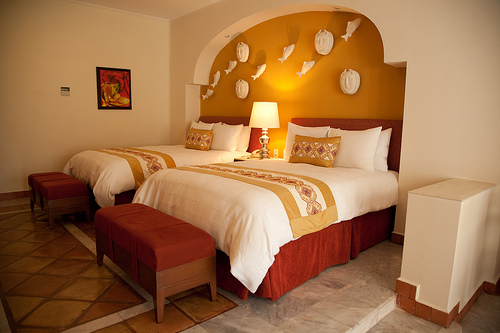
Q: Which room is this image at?
A: It is at the bedroom.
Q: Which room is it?
A: It is a bedroom.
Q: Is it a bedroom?
A: Yes, it is a bedroom.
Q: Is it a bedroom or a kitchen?
A: It is a bedroom.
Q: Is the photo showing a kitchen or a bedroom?
A: It is showing a bedroom.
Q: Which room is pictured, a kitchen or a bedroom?
A: It is a bedroom.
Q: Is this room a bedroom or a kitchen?
A: It is a bedroom.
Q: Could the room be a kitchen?
A: No, it is a bedroom.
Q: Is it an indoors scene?
A: Yes, it is indoors.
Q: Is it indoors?
A: Yes, it is indoors.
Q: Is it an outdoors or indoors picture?
A: It is indoors.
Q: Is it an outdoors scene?
A: No, it is indoors.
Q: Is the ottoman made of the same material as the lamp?
A: No, the ottoman is made of wood and the lamp is made of metal.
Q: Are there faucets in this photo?
A: No, there are no faucets.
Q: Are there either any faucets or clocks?
A: No, there are no faucets or clocks.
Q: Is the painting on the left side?
A: Yes, the painting is on the left of the image.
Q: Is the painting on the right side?
A: No, the painting is on the left of the image.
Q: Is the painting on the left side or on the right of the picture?
A: The painting is on the left of the image.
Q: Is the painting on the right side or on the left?
A: The painting is on the left of the image.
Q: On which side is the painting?
A: The painting is on the left of the image.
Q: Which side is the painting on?
A: The painting is on the left of the image.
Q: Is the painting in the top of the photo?
A: Yes, the painting is in the top of the image.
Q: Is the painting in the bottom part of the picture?
A: No, the painting is in the top of the image.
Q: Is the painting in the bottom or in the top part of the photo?
A: The painting is in the top of the image.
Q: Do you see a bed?
A: Yes, there is a bed.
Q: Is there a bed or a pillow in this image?
A: Yes, there is a bed.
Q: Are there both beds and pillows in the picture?
A: Yes, there are both a bed and a pillow.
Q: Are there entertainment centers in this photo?
A: No, there are no entertainment centers.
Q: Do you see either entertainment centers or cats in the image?
A: No, there are no entertainment centers or cats.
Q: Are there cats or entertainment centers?
A: No, there are no entertainment centers or cats.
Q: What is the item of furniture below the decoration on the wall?
A: The piece of furniture is a bed.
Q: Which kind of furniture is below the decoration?
A: The piece of furniture is a bed.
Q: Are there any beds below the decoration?
A: Yes, there is a bed below the decoration.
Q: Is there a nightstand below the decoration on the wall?
A: No, there is a bed below the decoration.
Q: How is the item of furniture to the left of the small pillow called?
A: The piece of furniture is a bed.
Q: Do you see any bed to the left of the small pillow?
A: Yes, there is a bed to the left of the pillow.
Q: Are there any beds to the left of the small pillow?
A: Yes, there is a bed to the left of the pillow.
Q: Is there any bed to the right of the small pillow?
A: No, the bed is to the left of the pillow.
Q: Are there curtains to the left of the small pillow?
A: No, there is a bed to the left of the pillow.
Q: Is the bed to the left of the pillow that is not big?
A: Yes, the bed is to the left of the pillow.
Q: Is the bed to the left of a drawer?
A: No, the bed is to the left of the pillow.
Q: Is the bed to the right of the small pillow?
A: No, the bed is to the left of the pillow.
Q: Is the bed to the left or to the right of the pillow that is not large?
A: The bed is to the left of the pillow.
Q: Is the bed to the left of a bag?
A: No, the bed is to the left of the pillow.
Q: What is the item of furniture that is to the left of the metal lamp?
A: The piece of furniture is a bed.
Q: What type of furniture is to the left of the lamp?
A: The piece of furniture is a bed.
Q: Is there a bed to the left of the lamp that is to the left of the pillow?
A: Yes, there is a bed to the left of the lamp.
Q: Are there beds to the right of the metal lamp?
A: No, the bed is to the left of the lamp.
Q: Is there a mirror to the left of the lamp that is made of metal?
A: No, there is a bed to the left of the lamp.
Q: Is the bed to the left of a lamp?
A: Yes, the bed is to the left of a lamp.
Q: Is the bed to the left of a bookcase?
A: No, the bed is to the left of a lamp.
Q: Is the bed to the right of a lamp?
A: No, the bed is to the left of a lamp.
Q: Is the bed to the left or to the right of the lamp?
A: The bed is to the left of the lamp.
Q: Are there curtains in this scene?
A: No, there are no curtains.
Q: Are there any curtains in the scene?
A: No, there are no curtains.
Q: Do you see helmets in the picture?
A: No, there are no helmets.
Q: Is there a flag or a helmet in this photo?
A: No, there are no helmets or flags.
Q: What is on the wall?
A: The decoration is on the wall.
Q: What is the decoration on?
A: The decoration is on the wall.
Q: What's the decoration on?
A: The decoration is on the wall.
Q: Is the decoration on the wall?
A: Yes, the decoration is on the wall.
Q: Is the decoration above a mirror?
A: No, the decoration is above a bed.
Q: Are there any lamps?
A: Yes, there is a lamp.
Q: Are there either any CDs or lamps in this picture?
A: Yes, there is a lamp.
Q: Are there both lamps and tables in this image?
A: Yes, there are both a lamp and a table.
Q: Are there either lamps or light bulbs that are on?
A: Yes, the lamp is on.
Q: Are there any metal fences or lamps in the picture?
A: Yes, there is a metal lamp.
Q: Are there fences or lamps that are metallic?
A: Yes, the lamp is metallic.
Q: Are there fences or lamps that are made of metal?
A: Yes, the lamp is made of metal.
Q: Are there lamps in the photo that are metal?
A: Yes, there is a metal lamp.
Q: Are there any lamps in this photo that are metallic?
A: Yes, there is a metal lamp.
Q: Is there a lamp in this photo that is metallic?
A: Yes, there is a lamp that is metallic.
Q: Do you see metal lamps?
A: Yes, there is a lamp that is made of metal.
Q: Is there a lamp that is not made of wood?
A: Yes, there is a lamp that is made of metal.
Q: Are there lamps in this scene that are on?
A: Yes, there is a lamp that is on.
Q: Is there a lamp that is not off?
A: Yes, there is a lamp that is on.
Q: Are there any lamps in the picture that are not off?
A: Yes, there is a lamp that is on.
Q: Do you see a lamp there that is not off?
A: Yes, there is a lamp that is on .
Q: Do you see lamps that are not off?
A: Yes, there is a lamp that is on .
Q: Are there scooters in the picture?
A: No, there are no scooters.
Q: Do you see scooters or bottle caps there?
A: No, there are no scooters or bottle caps.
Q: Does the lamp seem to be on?
A: Yes, the lamp is on.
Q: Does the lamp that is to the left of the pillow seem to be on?
A: Yes, the lamp is on.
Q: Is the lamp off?
A: No, the lamp is on.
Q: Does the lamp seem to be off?
A: No, the lamp is on.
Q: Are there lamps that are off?
A: No, there is a lamp but it is on.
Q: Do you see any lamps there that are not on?
A: No, there is a lamp but it is on.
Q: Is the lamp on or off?
A: The lamp is on.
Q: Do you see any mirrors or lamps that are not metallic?
A: No, there is a lamp but it is metallic.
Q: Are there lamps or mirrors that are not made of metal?
A: No, there is a lamp but it is made of metal.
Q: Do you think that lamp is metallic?
A: Yes, the lamp is metallic.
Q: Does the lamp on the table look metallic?
A: Yes, the lamp is metallic.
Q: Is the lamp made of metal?
A: Yes, the lamp is made of metal.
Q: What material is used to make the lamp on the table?
A: The lamp is made of metal.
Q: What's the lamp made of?
A: The lamp is made of metal.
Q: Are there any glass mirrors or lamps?
A: No, there is a lamp but it is metallic.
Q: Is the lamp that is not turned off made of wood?
A: No, the lamp is made of metal.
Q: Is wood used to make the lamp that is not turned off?
A: No, the lamp is made of metal.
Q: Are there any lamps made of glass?
A: No, there is a lamp but it is made of metal.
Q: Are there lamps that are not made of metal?
A: No, there is a lamp but it is made of metal.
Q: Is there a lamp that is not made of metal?
A: No, there is a lamp but it is made of metal.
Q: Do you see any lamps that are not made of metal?
A: No, there is a lamp but it is made of metal.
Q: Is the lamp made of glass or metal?
A: The lamp is made of metal.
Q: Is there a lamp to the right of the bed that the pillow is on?
A: Yes, there is a lamp to the right of the bed.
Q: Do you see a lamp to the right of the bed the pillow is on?
A: Yes, there is a lamp to the right of the bed.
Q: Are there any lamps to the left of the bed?
A: No, the lamp is to the right of the bed.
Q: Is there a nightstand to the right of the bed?
A: No, there is a lamp to the right of the bed.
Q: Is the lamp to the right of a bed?
A: Yes, the lamp is to the right of a bed.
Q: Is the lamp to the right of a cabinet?
A: No, the lamp is to the right of a bed.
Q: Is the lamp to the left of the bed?
A: No, the lamp is to the right of the bed.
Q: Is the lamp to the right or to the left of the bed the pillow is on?
A: The lamp is to the right of the bed.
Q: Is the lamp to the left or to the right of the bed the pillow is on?
A: The lamp is to the right of the bed.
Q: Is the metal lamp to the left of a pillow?
A: Yes, the lamp is to the left of a pillow.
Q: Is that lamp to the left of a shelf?
A: No, the lamp is to the left of a pillow.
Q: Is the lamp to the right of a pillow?
A: No, the lamp is to the left of a pillow.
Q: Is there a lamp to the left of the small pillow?
A: Yes, there is a lamp to the left of the pillow.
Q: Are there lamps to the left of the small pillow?
A: Yes, there is a lamp to the left of the pillow.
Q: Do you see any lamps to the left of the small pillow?
A: Yes, there is a lamp to the left of the pillow.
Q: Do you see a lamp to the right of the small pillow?
A: No, the lamp is to the left of the pillow.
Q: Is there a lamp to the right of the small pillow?
A: No, the lamp is to the left of the pillow.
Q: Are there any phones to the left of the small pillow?
A: No, there is a lamp to the left of the pillow.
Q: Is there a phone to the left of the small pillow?
A: No, there is a lamp to the left of the pillow.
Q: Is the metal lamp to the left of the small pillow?
A: Yes, the lamp is to the left of the pillow.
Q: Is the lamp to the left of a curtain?
A: No, the lamp is to the left of the pillow.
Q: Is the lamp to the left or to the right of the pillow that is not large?
A: The lamp is to the left of the pillow.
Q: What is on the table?
A: The lamp is on the table.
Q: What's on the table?
A: The lamp is on the table.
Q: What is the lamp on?
A: The lamp is on the table.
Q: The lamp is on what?
A: The lamp is on the table.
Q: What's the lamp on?
A: The lamp is on the table.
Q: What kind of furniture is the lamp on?
A: The lamp is on the table.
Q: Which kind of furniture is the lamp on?
A: The lamp is on the table.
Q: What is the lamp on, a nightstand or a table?
A: The lamp is on a table.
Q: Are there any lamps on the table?
A: Yes, there is a lamp on the table.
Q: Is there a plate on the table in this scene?
A: No, there is a lamp on the table.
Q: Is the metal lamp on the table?
A: Yes, the lamp is on the table.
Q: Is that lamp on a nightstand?
A: No, the lamp is on the table.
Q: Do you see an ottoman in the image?
A: Yes, there is an ottoman.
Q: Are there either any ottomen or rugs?
A: Yes, there is an ottoman.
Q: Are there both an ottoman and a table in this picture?
A: Yes, there are both an ottoman and a table.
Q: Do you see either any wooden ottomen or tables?
A: Yes, there is a wood ottoman.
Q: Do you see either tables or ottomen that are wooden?
A: Yes, the ottoman is wooden.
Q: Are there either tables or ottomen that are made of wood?
A: Yes, the ottoman is made of wood.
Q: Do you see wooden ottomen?
A: Yes, there is a wood ottoman.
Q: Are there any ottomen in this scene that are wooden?
A: Yes, there is an ottoman that is wooden.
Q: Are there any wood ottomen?
A: Yes, there is an ottoman that is made of wood.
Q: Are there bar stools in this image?
A: No, there are no bar stools.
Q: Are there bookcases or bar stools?
A: No, there are no bar stools or bookcases.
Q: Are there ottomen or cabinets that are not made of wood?
A: No, there is an ottoman but it is made of wood.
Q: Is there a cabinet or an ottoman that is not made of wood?
A: No, there is an ottoman but it is made of wood.